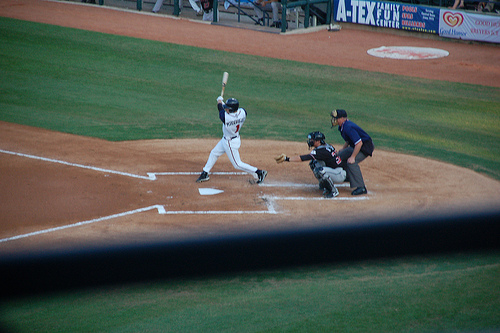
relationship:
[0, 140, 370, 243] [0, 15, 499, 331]
white markings on baseball field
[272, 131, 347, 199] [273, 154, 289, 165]
catcher wears brown glove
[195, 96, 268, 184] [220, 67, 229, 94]
batter swing bat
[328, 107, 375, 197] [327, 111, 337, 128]
umpire wearing facemask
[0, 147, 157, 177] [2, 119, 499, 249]
line in dirt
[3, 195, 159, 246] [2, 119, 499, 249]
line in dirt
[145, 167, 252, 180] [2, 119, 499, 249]
line in dirt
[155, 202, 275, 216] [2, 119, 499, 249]
line in dirt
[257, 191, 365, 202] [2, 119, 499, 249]
line in dirt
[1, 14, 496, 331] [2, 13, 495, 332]
grass on field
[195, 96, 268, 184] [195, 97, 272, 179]
batter wearing uniform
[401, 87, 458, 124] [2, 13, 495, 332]
grass on field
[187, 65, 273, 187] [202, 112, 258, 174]
batter wearing uniform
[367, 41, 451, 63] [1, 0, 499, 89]
white circle in red dirt